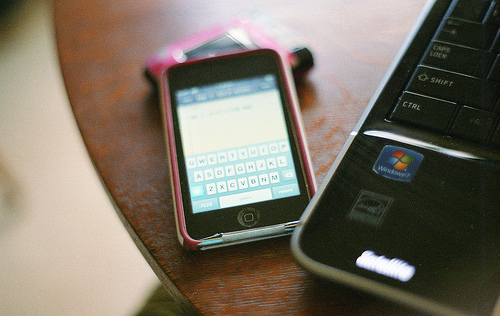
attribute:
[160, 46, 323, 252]
phone — red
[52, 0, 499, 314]
desk — wooden, brown, wood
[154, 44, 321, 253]
cover — red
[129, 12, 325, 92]
cellphone — red, pink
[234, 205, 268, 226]
button — round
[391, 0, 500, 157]
keyboard — black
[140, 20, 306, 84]
case — pink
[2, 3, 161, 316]
floor — white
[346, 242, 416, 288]
logo — illuminated